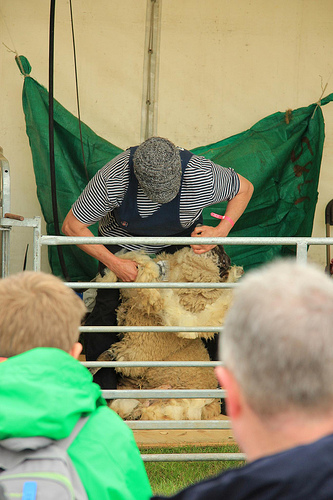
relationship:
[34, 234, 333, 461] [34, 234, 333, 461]
bar on bar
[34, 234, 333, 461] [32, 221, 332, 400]
bar on fence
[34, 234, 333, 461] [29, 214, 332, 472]
bar on fence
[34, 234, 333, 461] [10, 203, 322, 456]
bar on fence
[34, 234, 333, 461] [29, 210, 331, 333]
bar on fence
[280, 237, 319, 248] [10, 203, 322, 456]
bar on fence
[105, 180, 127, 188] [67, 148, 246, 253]
stripe on shirt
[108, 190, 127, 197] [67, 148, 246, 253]
stripe on shirt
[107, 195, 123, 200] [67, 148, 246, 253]
stripe on shirt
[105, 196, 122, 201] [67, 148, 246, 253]
stripe on shirt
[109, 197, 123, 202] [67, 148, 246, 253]
stripe on shirt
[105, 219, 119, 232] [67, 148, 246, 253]
stripe on shirt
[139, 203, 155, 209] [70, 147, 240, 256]
blue stripe on shirt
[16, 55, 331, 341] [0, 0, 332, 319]
fabric on wall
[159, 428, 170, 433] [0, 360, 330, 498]
stone on ground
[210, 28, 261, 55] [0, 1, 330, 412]
spots on wall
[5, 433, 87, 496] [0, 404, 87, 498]
backpack on back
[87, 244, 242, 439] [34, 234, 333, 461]
animal behind bar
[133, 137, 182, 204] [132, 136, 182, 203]
cap on a head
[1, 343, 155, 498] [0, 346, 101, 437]
jacket with a hood